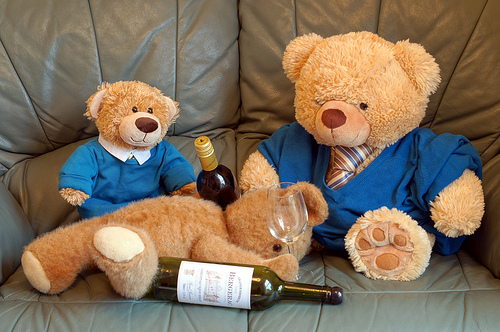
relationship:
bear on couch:
[58, 79, 198, 218] [6, 1, 498, 330]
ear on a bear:
[282, 27, 324, 74] [233, 30, 483, 288]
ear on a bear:
[391, 40, 441, 96] [233, 30, 483, 288]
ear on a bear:
[284, 179, 327, 222] [58, 79, 198, 218]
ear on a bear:
[82, 84, 103, 125] [58, 79, 198, 218]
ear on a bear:
[164, 93, 180, 127] [20, 181, 328, 298]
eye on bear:
[359, 102, 370, 111] [233, 30, 483, 288]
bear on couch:
[239, 29, 483, 282] [6, 1, 498, 330]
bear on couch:
[20, 181, 328, 302] [6, 1, 498, 330]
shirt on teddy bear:
[258, 120, 486, 258] [246, 27, 486, 279]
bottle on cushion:
[152, 253, 344, 311] [38, 215, 434, 324]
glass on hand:
[264, 181, 316, 285] [263, 252, 300, 282]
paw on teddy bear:
[342, 203, 438, 284] [246, 27, 486, 279]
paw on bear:
[85, 220, 154, 268] [38, 176, 302, 299]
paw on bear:
[9, 242, 61, 294] [21, 163, 371, 313]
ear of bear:
[391, 40, 441, 96] [233, 30, 483, 288]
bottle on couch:
[192, 135, 242, 211] [6, 1, 498, 330]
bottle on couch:
[151, 251, 346, 315] [6, 1, 498, 330]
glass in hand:
[264, 179, 316, 286] [169, 128, 233, 218]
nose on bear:
[309, 111, 350, 132] [253, 33, 483, 275]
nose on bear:
[309, 111, 350, 132] [58, 79, 198, 218]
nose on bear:
[321, 108, 348, 129] [233, 30, 483, 288]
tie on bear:
[323, 146, 370, 190] [233, 30, 483, 288]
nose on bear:
[321, 108, 348, 129] [232, 21, 495, 298]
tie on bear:
[327, 140, 378, 187] [233, 30, 483, 288]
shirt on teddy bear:
[258, 120, 480, 242] [246, 27, 486, 279]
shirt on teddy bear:
[61, 137, 196, 215] [26, 182, 332, 304]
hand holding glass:
[263, 251, 301, 283] [263, 179, 309, 283]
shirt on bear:
[258, 120, 486, 258] [232, 21, 495, 298]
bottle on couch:
[190, 131, 240, 203] [6, 1, 498, 330]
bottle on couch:
[152, 253, 344, 311] [6, 1, 498, 330]